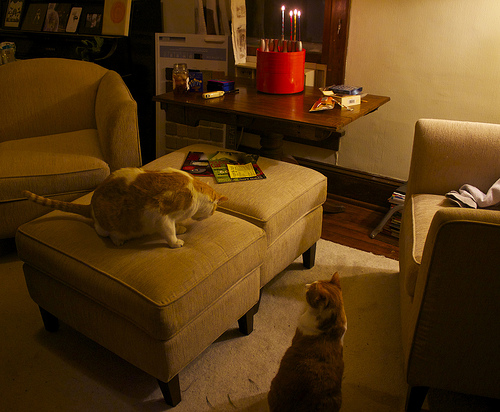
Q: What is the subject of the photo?
A: Cats.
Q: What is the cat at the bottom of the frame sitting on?
A: Carpet.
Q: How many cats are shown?
A: Two.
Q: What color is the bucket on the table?
A: Red.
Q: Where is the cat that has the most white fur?
A: On a stool.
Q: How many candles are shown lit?
A: Four.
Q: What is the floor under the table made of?
A: Wood.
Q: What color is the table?
A: Brown.